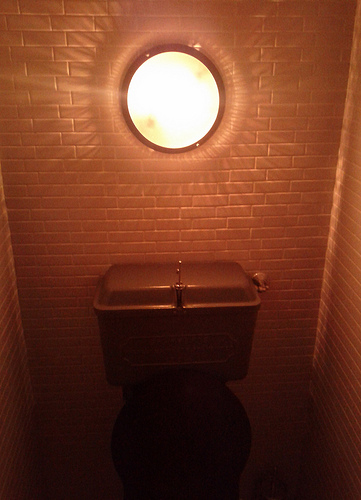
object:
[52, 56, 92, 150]
white bricks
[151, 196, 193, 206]
white brick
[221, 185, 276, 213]
bricks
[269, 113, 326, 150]
bricks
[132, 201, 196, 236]
bricks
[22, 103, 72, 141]
bricks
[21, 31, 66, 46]
brick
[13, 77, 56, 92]
brick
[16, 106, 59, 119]
brick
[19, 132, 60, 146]
brick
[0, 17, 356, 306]
wall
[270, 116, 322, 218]
bricks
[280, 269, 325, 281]
brick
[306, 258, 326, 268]
brick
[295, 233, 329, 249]
brick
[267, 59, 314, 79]
bricks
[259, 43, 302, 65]
bricks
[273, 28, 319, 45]
bricks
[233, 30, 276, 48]
bricks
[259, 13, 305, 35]
bricks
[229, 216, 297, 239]
bricks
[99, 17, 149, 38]
brick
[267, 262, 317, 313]
bricks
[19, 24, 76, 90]
bricks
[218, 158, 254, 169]
brick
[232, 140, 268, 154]
brick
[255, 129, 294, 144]
brick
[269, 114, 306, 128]
brick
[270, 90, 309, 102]
brick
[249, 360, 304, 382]
bricks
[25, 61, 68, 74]
brick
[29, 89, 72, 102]
brick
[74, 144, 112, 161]
brick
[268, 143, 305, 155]
brick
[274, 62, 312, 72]
brick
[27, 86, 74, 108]
bricks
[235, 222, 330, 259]
bricks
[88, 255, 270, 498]
toilet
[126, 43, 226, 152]
light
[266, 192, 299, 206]
brick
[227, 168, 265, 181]
brick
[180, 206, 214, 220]
brick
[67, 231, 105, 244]
brick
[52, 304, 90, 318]
brick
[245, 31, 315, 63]
bricks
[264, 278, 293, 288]
brick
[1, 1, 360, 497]
bathroom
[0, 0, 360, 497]
bricks